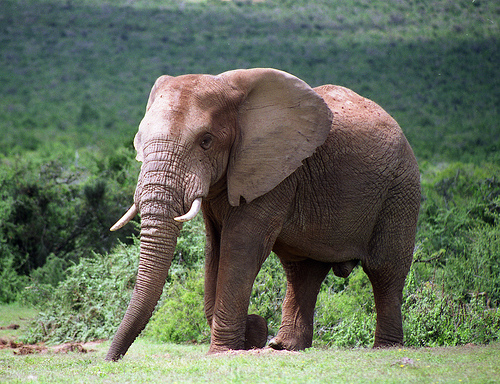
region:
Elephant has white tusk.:
[175, 187, 215, 222]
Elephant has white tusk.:
[98, 179, 163, 246]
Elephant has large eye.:
[179, 102, 235, 169]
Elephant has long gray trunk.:
[108, 230, 166, 329]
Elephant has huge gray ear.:
[242, 73, 312, 191]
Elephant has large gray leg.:
[219, 240, 249, 357]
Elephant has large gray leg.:
[271, 275, 323, 372]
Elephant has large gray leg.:
[352, 268, 409, 342]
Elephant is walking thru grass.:
[150, 295, 413, 372]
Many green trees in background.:
[377, 66, 453, 108]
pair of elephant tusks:
[109, 199, 210, 232]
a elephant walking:
[105, 65, 422, 362]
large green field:
[0, 0, 498, 348]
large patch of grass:
[0, 306, 499, 382]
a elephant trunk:
[103, 136, 197, 361]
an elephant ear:
[213, 65, 335, 207]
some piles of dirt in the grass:
[1, 318, 109, 358]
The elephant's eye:
[196, 129, 217, 151]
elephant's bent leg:
[202, 195, 270, 350]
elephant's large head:
[101, 65, 333, 360]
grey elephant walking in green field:
[87, 46, 433, 373]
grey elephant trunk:
[99, 198, 179, 365]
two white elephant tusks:
[100, 190, 205, 235]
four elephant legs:
[197, 232, 421, 359]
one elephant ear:
[218, 63, 336, 225]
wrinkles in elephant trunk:
[139, 193, 164, 271]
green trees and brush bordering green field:
[7, 130, 497, 344]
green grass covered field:
[162, 351, 497, 381]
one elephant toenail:
[260, 325, 295, 355]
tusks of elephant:
[98, 185, 216, 244]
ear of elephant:
[212, 47, 342, 218]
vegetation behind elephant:
[436, 225, 486, 332]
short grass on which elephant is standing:
[162, 348, 370, 377]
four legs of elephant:
[196, 290, 431, 362]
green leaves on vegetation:
[23, 117, 85, 227]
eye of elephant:
[190, 120, 224, 159]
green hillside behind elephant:
[77, 7, 350, 63]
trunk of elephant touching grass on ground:
[88, 330, 153, 379]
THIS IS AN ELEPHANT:
[99, 60, 429, 362]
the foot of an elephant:
[369, 228, 440, 348]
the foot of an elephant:
[279, 243, 323, 360]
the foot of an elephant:
[203, 225, 274, 360]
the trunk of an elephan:
[75, 177, 183, 362]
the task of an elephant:
[172, 195, 209, 231]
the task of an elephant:
[104, 194, 147, 239]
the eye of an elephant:
[186, 125, 222, 160]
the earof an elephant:
[218, 51, 328, 227]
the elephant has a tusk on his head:
[173, 192, 203, 222]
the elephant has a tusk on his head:
[109, 199, 138, 232]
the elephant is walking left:
[78, 63, 424, 362]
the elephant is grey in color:
[83, 68, 418, 366]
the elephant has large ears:
[224, 64, 336, 204]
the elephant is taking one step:
[204, 208, 283, 360]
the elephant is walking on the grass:
[103, 58, 422, 365]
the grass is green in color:
[3, 341, 498, 382]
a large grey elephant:
[98, 64, 420, 361]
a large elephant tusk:
[173, 195, 203, 220]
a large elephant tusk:
[107, 202, 134, 232]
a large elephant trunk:
[107, 192, 182, 362]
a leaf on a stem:
[332, 324, 334, 332]